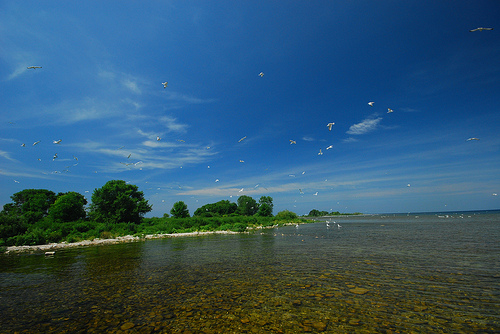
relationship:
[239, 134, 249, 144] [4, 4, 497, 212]
bird in sky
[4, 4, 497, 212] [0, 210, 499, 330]
sky over water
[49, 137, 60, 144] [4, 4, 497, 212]
bird in sky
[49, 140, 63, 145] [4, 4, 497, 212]
bird in sky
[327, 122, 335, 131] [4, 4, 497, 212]
bird in sky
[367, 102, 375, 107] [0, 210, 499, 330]
bird flying over water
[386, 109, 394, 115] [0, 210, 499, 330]
bird flying over water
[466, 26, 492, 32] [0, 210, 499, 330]
bird flying over water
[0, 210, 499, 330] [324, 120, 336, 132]
water flying over bird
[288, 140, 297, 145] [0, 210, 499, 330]
bird flying over water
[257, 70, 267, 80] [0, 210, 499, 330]
bird flying over water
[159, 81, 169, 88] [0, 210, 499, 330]
bird flying over water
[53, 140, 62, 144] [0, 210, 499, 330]
bird flying over water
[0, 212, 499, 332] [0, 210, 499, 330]
rocks next to water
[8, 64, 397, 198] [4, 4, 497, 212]
birds flying in sky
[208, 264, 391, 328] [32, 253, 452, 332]
rocks on bottom of water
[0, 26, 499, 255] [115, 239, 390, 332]
birds on water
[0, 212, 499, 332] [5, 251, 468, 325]
rocks on bottom of water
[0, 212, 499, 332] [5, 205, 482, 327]
rocks in water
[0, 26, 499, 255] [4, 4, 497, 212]
birds in sky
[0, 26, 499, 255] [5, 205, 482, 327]
birds on water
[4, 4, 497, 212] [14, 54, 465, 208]
sky with clouds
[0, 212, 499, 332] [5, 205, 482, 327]
rocks under water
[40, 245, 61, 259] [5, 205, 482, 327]
log on water